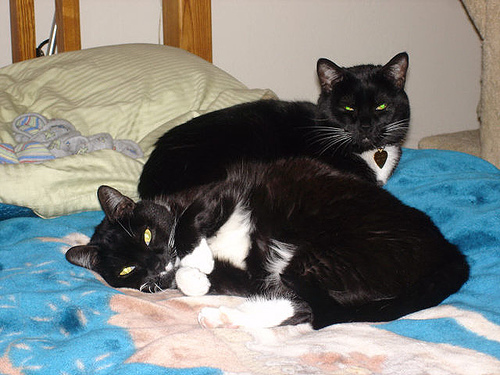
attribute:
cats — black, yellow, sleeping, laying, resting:
[250, 62, 411, 329]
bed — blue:
[445, 156, 499, 228]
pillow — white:
[108, 39, 176, 106]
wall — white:
[251, 8, 282, 44]